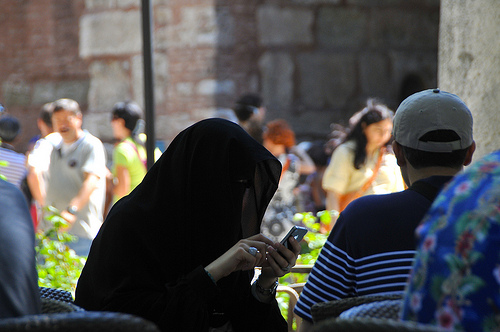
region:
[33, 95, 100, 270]
a person is standing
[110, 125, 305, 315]
a person is standing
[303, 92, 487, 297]
a person is standing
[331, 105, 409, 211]
a person is standing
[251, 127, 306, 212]
a person is standing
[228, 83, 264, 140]
a person is standing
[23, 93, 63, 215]
a person is standing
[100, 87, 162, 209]
a person is standing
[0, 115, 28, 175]
a person is standing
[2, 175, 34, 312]
a person is standing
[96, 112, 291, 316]
woman covered in black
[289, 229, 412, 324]
stripes on short sleeved shirt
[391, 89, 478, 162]
back of hat on man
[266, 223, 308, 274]
hand holding cell phone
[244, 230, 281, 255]
finger on face of cell phone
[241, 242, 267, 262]
ring on woman's hand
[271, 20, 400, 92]
stones on building wall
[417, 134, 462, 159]
strap on back of hat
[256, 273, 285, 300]
watch on woman's wrist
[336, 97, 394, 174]
woman with black hair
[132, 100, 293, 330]
person completely covered up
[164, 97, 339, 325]
person on cell phone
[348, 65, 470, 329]
person wearing white ball ap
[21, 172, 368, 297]
leaves visible in photograph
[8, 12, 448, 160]
brick building in photograph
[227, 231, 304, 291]
woman wearing blue ring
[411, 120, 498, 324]
person in blue flowered shirt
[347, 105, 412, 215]
woman with black hair walking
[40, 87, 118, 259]
man standing in grey shirt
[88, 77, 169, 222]
man in yellow shirt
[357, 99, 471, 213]
A man wearing a hat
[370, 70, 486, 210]
A man wearing a white hat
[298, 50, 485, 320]
A man wearing a blue shirt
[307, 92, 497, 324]
A man wearing a striped shirt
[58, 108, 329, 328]
A Muslim woman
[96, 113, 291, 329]
A woman wearing a black garment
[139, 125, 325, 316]
A woman holding a phone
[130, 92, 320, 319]
A woman holding an iPhone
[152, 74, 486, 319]
A woman and man sitting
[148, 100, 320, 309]
A woman looking at a phone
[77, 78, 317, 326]
a women wearing a black offit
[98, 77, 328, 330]
a women covering her head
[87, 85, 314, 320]
a women texting on her phone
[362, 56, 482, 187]
a man wearing a white hat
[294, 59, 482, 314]
a man wearing a black and white striped shirt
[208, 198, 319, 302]
someone holding a phone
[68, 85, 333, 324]
a women covering her face with a black garment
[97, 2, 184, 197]
a tall pole in the street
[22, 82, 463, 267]
a crowd of people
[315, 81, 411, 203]
a women wearing a bag